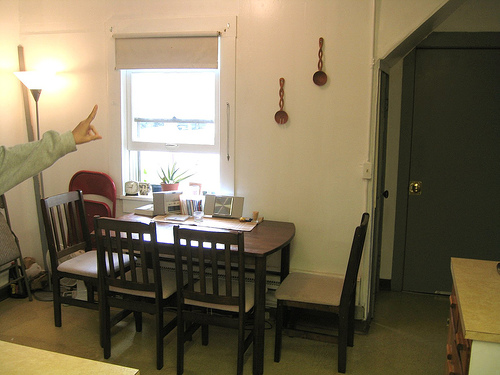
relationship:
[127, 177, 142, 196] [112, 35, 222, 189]
clock on window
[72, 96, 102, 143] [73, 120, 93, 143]
fingers on hand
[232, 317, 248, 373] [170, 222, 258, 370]
leg of a chair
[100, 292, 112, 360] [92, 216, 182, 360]
leg of a chair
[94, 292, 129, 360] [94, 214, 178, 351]
leg of a chair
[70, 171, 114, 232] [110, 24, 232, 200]
chair to left of window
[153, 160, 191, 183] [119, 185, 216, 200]
plant on windowsill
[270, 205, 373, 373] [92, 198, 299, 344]
chair under table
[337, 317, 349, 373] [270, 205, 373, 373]
leg on chair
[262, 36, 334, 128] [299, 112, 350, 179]
spoons on wall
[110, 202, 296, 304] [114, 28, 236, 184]
table in front of window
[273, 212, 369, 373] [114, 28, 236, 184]
chair in front of window